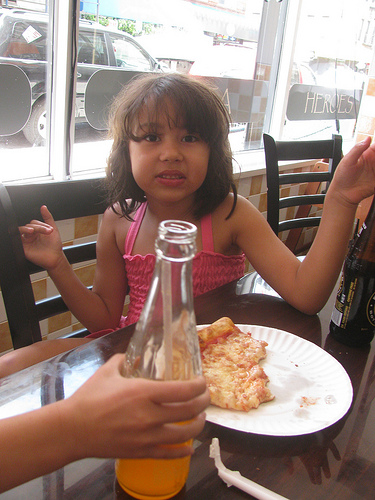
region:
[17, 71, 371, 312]
Girl sitting at the table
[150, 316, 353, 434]
Partially-eaten slice of pizza on a paper plate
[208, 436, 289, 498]
Empty straw wrapper on the table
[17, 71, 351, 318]
Little girl wearing a pink dress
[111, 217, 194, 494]
Bottle of orange soda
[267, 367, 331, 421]
Grease marks on the paper plate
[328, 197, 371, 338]
Glass bottle to right of the girl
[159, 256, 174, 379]
Plastic straw in the soda bottle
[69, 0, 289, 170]
Window behind the girl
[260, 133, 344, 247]
Chair in front of the window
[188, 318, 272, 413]
part of a pizza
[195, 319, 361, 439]
part of a white paper plate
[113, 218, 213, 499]
a tall glass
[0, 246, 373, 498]
part of a table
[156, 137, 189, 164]
the nose of a girl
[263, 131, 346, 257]
part of a wooden chair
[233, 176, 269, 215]
a colorful wall tile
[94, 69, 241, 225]
a girl's brown hair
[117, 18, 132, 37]
green tree leaves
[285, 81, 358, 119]
A sign for heroes on a dark surface.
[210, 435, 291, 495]
A white straw wrapping on a surface.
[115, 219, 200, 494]
A straw is inside a bottle.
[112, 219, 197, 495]
A bottle has orange drink in it.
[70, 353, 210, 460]
A hand is wrapped around a glass.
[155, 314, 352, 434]
A partly eaten sliceof pizza is on a plate.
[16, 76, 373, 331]
A girl is wearing a pink top.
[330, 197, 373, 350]
A bottle is brown with labels.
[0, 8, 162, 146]
A car is outside a window.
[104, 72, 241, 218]
A girl has dark hair.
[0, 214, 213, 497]
A person is holding onto a bottle.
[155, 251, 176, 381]
A straw is in a bottle.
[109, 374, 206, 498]
A yellow liquid is in a bottle.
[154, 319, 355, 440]
A paper plate is on a table.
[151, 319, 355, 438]
The color of a paper plate is white.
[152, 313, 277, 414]
Some food is on a plate.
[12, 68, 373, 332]
A girl has her hands in the air.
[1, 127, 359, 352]
Two chairs are next to a table.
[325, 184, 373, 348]
A bottle is sitting on a table.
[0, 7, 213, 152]
A vehicle is outside a window.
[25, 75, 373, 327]
a young girl sitting by the restaurant table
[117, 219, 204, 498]
an open bottle of orange soda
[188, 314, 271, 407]
a slice of cheese pizza sitting on the paper plate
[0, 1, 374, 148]
the front windows of the restaurant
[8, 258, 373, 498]
the table the food and drinks are sitting on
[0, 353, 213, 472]
the hand holding onto the orange soda bottle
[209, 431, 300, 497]
the empty straw wrapper sitting on the table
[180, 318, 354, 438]
the paper plate the pizza is sitting on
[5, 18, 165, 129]
a car parked outside the restaurant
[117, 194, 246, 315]
the pink outfit the girl is wearing